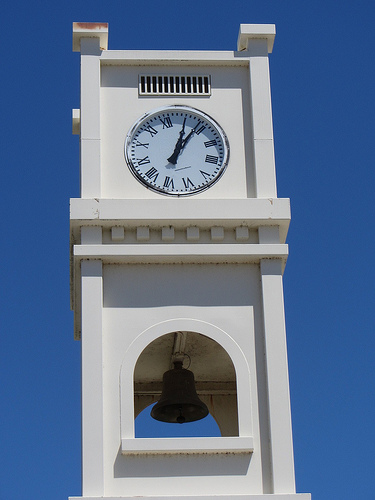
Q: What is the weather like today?
A: It is clear.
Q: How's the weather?
A: It is clear.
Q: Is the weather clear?
A: Yes, it is clear.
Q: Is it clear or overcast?
A: It is clear.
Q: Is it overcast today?
A: No, it is clear.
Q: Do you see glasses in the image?
A: No, there are no glasses.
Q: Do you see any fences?
A: No, there are no fences.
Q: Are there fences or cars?
A: No, there are no fences or cars.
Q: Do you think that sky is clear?
A: Yes, the sky is clear.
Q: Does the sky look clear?
A: Yes, the sky is clear.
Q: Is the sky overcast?
A: No, the sky is clear.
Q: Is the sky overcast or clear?
A: The sky is clear.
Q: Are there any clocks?
A: Yes, there is a clock.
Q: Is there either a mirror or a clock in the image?
A: Yes, there is a clock.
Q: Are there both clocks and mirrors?
A: No, there is a clock but no mirrors.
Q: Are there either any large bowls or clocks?
A: Yes, there is a large clock.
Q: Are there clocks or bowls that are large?
A: Yes, the clock is large.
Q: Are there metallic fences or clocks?
A: Yes, there is a metal clock.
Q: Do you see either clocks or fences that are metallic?
A: Yes, the clock is metallic.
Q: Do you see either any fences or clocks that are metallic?
A: Yes, the clock is metallic.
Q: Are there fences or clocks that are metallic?
A: Yes, the clock is metallic.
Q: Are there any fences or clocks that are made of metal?
A: Yes, the clock is made of metal.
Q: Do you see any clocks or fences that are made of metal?
A: Yes, the clock is made of metal.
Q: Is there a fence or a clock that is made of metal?
A: Yes, the clock is made of metal.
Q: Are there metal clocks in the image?
A: Yes, there is a metal clock.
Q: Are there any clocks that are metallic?
A: Yes, there is a clock that is metallic.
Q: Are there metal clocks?
A: Yes, there is a clock that is made of metal.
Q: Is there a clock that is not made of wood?
A: Yes, there is a clock that is made of metal.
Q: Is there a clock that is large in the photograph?
A: Yes, there is a large clock.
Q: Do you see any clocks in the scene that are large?
A: Yes, there is a clock that is large.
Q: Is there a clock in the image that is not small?
A: Yes, there is a large clock.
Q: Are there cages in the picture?
A: No, there are no cages.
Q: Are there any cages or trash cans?
A: No, there are no cages or trash cans.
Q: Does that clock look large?
A: Yes, the clock is large.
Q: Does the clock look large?
A: Yes, the clock is large.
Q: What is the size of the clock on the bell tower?
A: The clock is large.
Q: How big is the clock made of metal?
A: The clock is large.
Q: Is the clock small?
A: No, the clock is large.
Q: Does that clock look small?
A: No, the clock is large.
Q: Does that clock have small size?
A: No, the clock is large.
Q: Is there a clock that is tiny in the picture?
A: No, there is a clock but it is large.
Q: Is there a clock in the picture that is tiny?
A: No, there is a clock but it is large.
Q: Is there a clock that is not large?
A: No, there is a clock but it is large.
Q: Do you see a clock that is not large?
A: No, there is a clock but it is large.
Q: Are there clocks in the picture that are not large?
A: No, there is a clock but it is large.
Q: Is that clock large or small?
A: The clock is large.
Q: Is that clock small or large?
A: The clock is large.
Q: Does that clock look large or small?
A: The clock is large.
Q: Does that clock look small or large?
A: The clock is large.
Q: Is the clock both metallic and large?
A: Yes, the clock is metallic and large.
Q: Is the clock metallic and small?
A: No, the clock is metallic but large.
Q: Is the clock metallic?
A: Yes, the clock is metallic.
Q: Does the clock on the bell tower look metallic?
A: Yes, the clock is metallic.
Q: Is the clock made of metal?
A: Yes, the clock is made of metal.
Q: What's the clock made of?
A: The clock is made of metal.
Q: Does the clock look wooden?
A: No, the clock is metallic.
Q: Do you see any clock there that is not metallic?
A: No, there is a clock but it is metallic.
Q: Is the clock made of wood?
A: No, the clock is made of metal.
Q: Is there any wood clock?
A: No, there is a clock but it is made of metal.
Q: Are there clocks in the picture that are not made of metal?
A: No, there is a clock but it is made of metal.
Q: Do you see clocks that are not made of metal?
A: No, there is a clock but it is made of metal.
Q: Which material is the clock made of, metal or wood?
A: The clock is made of metal.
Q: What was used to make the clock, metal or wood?
A: The clock is made of metal.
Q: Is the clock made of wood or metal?
A: The clock is made of metal.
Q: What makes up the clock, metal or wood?
A: The clock is made of metal.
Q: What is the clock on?
A: The clock is on the bell tower.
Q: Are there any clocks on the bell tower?
A: Yes, there is a clock on the bell tower.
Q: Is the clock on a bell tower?
A: Yes, the clock is on a bell tower.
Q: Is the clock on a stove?
A: No, the clock is on a bell tower.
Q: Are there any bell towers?
A: Yes, there is a bell tower.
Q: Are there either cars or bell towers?
A: Yes, there is a bell tower.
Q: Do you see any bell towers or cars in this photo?
A: Yes, there is a bell tower.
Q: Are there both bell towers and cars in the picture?
A: No, there is a bell tower but no cars.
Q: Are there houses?
A: No, there are no houses.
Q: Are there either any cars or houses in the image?
A: No, there are no houses or cars.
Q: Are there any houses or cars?
A: No, there are no houses or cars.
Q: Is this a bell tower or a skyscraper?
A: This is a bell tower.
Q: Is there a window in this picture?
A: Yes, there is a window.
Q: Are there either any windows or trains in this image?
A: Yes, there is a window.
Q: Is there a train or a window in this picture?
A: Yes, there is a window.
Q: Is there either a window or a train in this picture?
A: Yes, there is a window.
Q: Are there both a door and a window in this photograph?
A: No, there is a window but no doors.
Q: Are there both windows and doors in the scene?
A: No, there is a window but no doors.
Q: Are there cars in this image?
A: No, there are no cars.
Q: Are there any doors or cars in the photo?
A: No, there are no cars or doors.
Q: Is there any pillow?
A: No, there are no pillows.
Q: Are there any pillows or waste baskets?
A: No, there are no pillows or waste baskets.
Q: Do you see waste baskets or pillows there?
A: No, there are no pillows or waste baskets.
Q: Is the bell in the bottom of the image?
A: Yes, the bell is in the bottom of the image.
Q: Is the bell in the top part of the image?
A: No, the bell is in the bottom of the image.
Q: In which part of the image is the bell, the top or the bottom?
A: The bell is in the bottom of the image.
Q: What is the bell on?
A: The bell is on the bell tower.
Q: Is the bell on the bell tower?
A: Yes, the bell is on the bell tower.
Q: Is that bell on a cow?
A: No, the bell is on the bell tower.